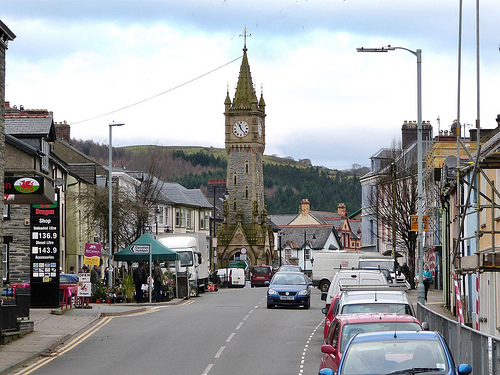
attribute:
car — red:
[324, 312, 433, 373]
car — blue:
[264, 269, 314, 310]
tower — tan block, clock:
[215, 22, 272, 279]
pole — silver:
[416, 47, 421, 294]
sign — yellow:
[408, 209, 429, 232]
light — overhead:
[352, 42, 424, 309]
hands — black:
[237, 122, 245, 132]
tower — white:
[204, 29, 305, 273]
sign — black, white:
[130, 245, 149, 253]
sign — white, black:
[82, 242, 99, 266]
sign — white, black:
[76, 282, 89, 295]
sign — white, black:
[3, 177, 43, 192]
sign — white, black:
[30, 204, 57, 282]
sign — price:
[25, 183, 66, 309]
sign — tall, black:
[28, 187, 60, 309]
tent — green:
[110, 226, 178, 298]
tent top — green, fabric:
[116, 229, 181, 264]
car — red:
[315, 311, 449, 371]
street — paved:
[16, 276, 331, 373]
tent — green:
[112, 227, 187, 304]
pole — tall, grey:
[328, 24, 481, 309]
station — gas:
[3, 181, 66, 323]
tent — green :
[124, 226, 198, 296]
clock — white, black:
[228, 118, 253, 147]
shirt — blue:
[421, 265, 433, 279]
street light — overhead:
[102, 116, 125, 305]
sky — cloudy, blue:
[22, 11, 220, 103]